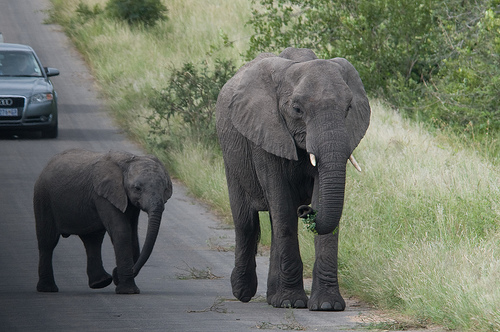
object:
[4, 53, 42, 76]
man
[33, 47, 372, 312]
elephants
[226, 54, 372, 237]
head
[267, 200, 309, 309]
leg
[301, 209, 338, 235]
branch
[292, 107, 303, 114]
eye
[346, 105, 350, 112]
eye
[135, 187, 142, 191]
eye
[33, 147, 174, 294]
elephant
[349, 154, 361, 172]
elephant tusk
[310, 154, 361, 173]
tusks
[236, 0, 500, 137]
bush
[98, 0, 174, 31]
bush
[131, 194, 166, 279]
trunk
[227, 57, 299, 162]
ear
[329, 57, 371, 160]
ear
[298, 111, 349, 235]
elephant nose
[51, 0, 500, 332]
grass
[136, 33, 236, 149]
brush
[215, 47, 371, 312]
elephant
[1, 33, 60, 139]
audi car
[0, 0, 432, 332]
paved road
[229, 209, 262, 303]
leg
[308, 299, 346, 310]
toes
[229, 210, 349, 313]
legs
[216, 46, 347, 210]
body